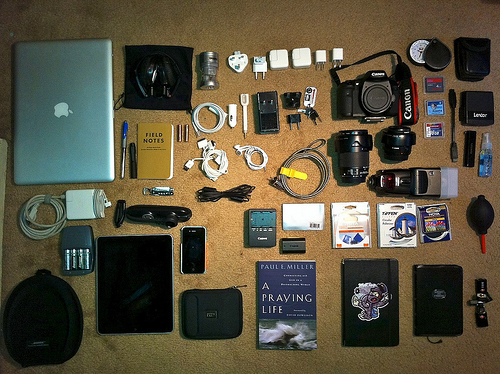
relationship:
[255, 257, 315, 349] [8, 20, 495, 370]
book on rug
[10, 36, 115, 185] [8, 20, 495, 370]
laptop on rug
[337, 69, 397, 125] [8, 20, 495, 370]
camera on rug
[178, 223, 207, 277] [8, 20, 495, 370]
cell phone on rug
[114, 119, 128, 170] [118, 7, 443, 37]
pen on rug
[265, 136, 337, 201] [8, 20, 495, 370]
cord on rug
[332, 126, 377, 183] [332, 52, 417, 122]
camera lens below camera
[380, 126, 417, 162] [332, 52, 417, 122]
camera lens below camera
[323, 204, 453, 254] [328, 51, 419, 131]
packages below camera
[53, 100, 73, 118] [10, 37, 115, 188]
logo on computer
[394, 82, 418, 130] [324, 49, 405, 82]
lettering on strap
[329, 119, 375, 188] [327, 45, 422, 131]
lens next to camera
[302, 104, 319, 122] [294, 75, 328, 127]
keys on key chain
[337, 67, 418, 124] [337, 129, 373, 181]
camera has lens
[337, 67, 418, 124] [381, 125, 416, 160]
camera has lens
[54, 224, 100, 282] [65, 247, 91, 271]
charger with batteries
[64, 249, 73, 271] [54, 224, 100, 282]
battery in charger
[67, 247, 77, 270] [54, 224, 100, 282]
battery in charger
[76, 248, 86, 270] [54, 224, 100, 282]
battery in charger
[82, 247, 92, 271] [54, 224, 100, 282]
battery in charger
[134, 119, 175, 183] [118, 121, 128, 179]
notebook next to pen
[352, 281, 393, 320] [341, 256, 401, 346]
sticker on wallet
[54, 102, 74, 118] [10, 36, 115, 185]
logo on laptop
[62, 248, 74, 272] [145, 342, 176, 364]
battery on rug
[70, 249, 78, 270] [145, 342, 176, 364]
battery on rug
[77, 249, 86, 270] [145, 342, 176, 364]
battery on rug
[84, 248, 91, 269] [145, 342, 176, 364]
battery on rug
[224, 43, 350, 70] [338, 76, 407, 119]
electrical adapters to left of camera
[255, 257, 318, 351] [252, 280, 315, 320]
book with title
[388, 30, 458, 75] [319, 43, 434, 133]
compass to right of camera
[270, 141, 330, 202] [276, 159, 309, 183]
grey cord rolled up with yellow tie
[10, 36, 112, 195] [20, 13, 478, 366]
laptop on surface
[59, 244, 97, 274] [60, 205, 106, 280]
batteries in charger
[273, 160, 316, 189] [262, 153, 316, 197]
strap holding wiring